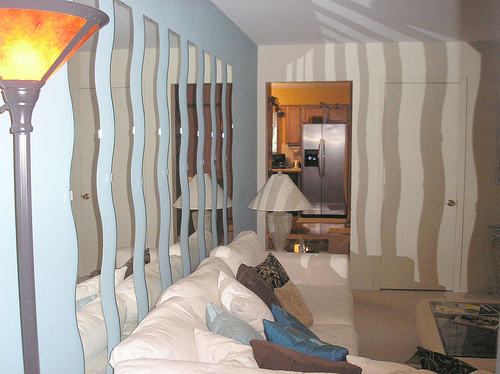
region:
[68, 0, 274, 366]
mirrors on the wall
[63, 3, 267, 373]
row of squiggly mirrors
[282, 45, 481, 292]
brown and white stripes on the wall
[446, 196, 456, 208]
small doorknob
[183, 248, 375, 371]
several pillows on the couch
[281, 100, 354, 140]
cabinets on the wall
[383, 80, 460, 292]
brown and white stripes on the door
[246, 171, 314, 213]
brown and white stripes on the lampshade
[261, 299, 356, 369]
two dark blue pillows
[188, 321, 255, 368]
white pillow in the corner of the couch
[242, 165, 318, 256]
a white lamp with reflecting stripes on it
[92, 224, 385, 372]
a couch with multiple pillows on it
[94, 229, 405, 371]
a davenport with pillows on it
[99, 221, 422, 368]
a sofa with pillows on it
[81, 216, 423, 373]
a white couch with pillows on it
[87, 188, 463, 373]
a white davenport with pillos on it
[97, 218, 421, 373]
a white sofa with pillows on it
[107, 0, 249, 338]
mirror strips used as a wall-hanging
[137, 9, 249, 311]
decorative mirrors on a wall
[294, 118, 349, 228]
a stainless steel refrigerator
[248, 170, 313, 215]
Small White table lampshade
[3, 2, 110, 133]
Large orange pole lampshade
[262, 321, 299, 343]
Part of teal sofa pillow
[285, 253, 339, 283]
Arm of white couch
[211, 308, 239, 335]
Part of light blue pillow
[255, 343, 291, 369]
Part of brown pillow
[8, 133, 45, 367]
Pole for floor lamp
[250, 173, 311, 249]
Small lamp on end table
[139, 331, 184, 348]
Back section of white couch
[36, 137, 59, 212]
Part of blue wall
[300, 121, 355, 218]
Chrome refrigerator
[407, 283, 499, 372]
part of a cream coffee table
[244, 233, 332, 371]
Throw pillows on a sofa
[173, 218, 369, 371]
Throw pillows on a white sofa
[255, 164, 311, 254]
Cream table lamp with shade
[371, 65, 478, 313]
White door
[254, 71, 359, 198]
Mirror with a fridge reflection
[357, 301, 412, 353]
Part of a cream carpet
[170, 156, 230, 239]
Reflection of a table lamp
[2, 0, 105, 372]
Part of a floor lamp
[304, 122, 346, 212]
Grey refriderator with black ice maker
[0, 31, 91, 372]
Thin tall grey lamp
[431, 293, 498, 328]
Three magazines on table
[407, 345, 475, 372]
Black designed pillow on couch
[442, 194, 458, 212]
Small door knob on white door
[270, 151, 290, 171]
Black coffee maker on counter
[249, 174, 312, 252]
White lamp with shadow on it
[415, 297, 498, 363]
Glass coffee table with magazines on top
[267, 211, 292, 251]
Bottom half of a lamp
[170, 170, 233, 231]
Reflection of a lamp